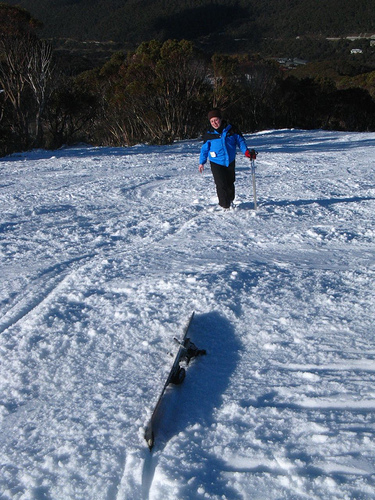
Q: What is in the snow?
A: A ski.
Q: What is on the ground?
A: Snow.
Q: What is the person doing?
A: Walking in the snow.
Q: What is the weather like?
A: Sunny.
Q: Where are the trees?
A: Behind person.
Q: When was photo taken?
A: During the daytime.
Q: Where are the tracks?
A: In the snow.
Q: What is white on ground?
A: Snow.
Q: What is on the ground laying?
A: A ski.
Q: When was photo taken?
A: Winter.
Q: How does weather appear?
A: Cold.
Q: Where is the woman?
A: Snowy ski slope.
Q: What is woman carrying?
A: The other ski.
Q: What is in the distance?
A: Hills.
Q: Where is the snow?
A: On ground.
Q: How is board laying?
A: On side.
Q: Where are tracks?
A: In snow.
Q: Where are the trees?
A: In distance.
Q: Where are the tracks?
A: In the snow.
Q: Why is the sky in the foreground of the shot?
A: The photographer is standing right next to it.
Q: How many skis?
A: One.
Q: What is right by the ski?
A: Its shadow.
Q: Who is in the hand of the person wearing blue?
A: Ski poles.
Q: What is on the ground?
A: Snow.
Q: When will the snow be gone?
A: When the sun melts it.